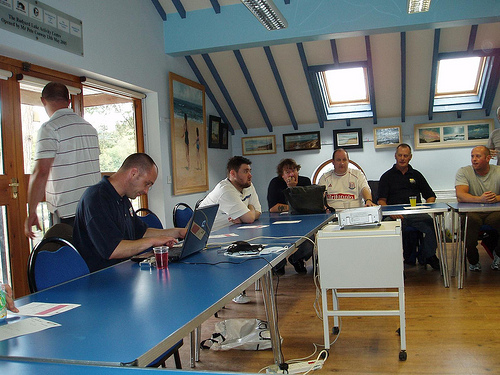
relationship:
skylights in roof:
[199, 20, 497, 179] [155, 22, 486, 137]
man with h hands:
[445, 132, 497, 273] [478, 185, 497, 207]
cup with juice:
[148, 241, 176, 277] [408, 195, 431, 228]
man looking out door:
[12, 73, 113, 276] [11, 65, 174, 307]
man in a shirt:
[368, 124, 493, 311] [377, 167, 434, 199]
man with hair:
[188, 122, 286, 296] [199, 148, 263, 229]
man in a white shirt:
[194, 150, 261, 303] [198, 179, 258, 233]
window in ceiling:
[315, 62, 375, 121] [164, 1, 495, 121]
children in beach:
[179, 108, 193, 171] [173, 114, 204, 189]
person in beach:
[192, 127, 203, 172] [173, 114, 204, 189]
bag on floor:
[200, 316, 285, 351] [157, 256, 499, 373]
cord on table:
[253, 229, 297, 246] [152, 265, 264, 325]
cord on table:
[224, 252, 273, 269] [152, 265, 264, 325]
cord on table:
[300, 334, 325, 361] [152, 265, 264, 325]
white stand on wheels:
[318, 219, 407, 361] [322, 327, 406, 357]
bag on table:
[281, 182, 336, 217] [2, 195, 499, 374]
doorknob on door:
[8, 179, 18, 197] [0, 79, 26, 300]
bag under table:
[206, 316, 285, 358] [53, 243, 301, 372]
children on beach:
[164, 108, 225, 205] [159, 55, 253, 206]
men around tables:
[16, 73, 126, 248] [2, 173, 354, 355]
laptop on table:
[128, 200, 234, 263] [6, 195, 347, 374]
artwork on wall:
[166, 68, 226, 212] [131, 41, 256, 249]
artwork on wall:
[237, 134, 277, 156] [226, 128, 496, 195]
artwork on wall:
[279, 131, 321, 152] [226, 128, 496, 195]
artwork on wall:
[329, 126, 364, 150] [226, 128, 496, 195]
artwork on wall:
[368, 123, 402, 150] [226, 128, 496, 195]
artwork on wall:
[412, 118, 496, 150] [226, 128, 496, 195]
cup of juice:
[407, 195, 416, 205] [397, 194, 429, 210]